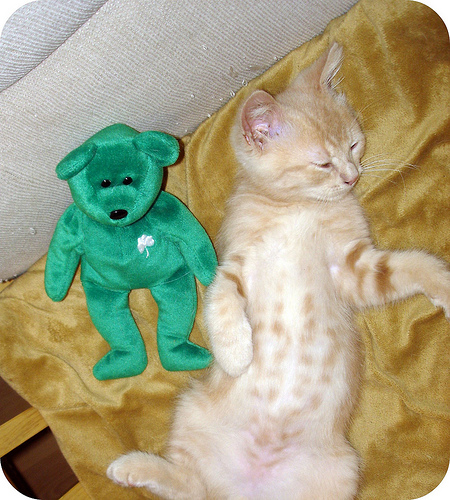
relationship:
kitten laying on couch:
[107, 45, 418, 498] [0, 2, 446, 497]